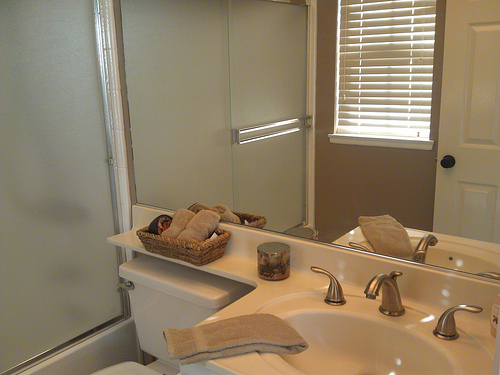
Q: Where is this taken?
A: A bathroom.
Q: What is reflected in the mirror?
A: A window and a door.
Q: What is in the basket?
A: Hand towels.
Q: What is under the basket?
A: A toilet.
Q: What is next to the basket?
A: A candle.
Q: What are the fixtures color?
A: Nickel finish.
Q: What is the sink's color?
A: Bisque.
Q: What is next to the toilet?
A: A show and tub.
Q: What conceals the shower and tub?
A: A glass sliding door.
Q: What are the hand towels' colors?
A: Brown.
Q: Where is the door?
A: In the mirror.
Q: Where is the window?
A: In the mirror.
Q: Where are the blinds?
A: In the mirror.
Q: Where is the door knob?
A: On the door.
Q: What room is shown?
A: Bathroom.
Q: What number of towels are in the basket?
A: 2.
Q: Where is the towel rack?
A: On the shower door.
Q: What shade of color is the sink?
A: White.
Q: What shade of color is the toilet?
A: White.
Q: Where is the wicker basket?
A: On the counter.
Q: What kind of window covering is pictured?
A: Blinds.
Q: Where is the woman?
A: There is no woman.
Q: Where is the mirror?
A: On the wall.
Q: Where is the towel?
A: On the sink.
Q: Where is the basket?
A: On the toilet tank.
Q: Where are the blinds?
A: On the window.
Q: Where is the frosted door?
A: On the shower.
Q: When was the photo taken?
A: Daytime.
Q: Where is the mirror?
A: Behind the sink.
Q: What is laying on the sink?
A: Towel.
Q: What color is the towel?
A: Brown.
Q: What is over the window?
A: Blinds.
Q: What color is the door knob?
A: Black.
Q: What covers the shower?
A: Glass.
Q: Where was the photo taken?
A: In a bathroom.